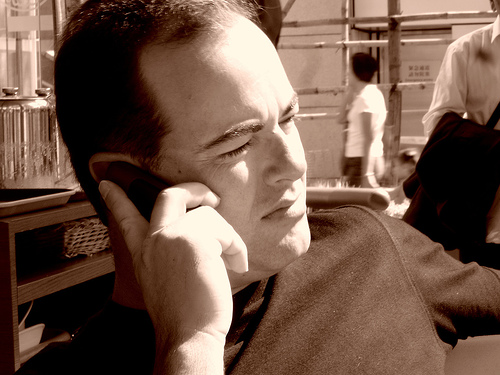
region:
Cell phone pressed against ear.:
[100, 157, 180, 224]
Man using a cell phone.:
[48, 0, 498, 374]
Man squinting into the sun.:
[54, 0, 321, 337]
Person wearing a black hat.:
[337, 51, 389, 193]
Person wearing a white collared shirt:
[413, 1, 498, 270]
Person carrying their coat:
[394, 1, 499, 266]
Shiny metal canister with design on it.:
[0, 82, 63, 189]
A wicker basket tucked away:
[54, 214, 114, 264]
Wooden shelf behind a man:
[3, 195, 137, 373]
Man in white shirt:
[334, 41, 389, 202]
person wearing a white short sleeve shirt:
[340, 53, 387, 187]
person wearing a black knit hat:
[352, 50, 379, 82]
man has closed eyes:
[18, 0, 499, 374]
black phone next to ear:
[105, 160, 172, 220]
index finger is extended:
[96, 179, 146, 250]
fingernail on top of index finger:
[96, 180, 108, 193]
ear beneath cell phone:
[86, 155, 137, 185]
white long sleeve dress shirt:
[419, 13, 499, 140]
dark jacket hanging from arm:
[401, 111, 499, 261]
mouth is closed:
[257, 191, 308, 217]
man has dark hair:
[25, 11, 207, 182]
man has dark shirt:
[111, 174, 438, 349]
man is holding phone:
[86, 133, 239, 268]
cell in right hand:
[75, 155, 232, 262]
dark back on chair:
[1, 188, 91, 350]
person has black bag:
[411, 103, 496, 263]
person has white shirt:
[437, 23, 492, 121]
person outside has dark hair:
[346, 44, 396, 86]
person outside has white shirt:
[342, 87, 401, 180]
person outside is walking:
[334, 44, 399, 178]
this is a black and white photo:
[26, 16, 418, 329]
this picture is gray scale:
[42, 36, 389, 361]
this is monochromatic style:
[16, 49, 364, 327]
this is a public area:
[19, 13, 418, 264]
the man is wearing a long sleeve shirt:
[309, 257, 455, 339]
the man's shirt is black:
[312, 241, 400, 373]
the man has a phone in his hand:
[113, 114, 218, 264]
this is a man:
[72, 54, 384, 336]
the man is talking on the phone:
[123, 154, 208, 234]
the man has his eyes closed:
[167, 101, 312, 168]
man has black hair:
[86, 89, 110, 116]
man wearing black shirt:
[316, 283, 370, 340]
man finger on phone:
[99, 184, 126, 211]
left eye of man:
[214, 127, 259, 169]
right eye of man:
[278, 103, 303, 135]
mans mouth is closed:
[260, 195, 316, 229]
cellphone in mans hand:
[93, 164, 253, 308]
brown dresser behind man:
[28, 218, 48, 229]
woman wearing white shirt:
[356, 116, 363, 133]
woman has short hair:
[360, 57, 370, 68]